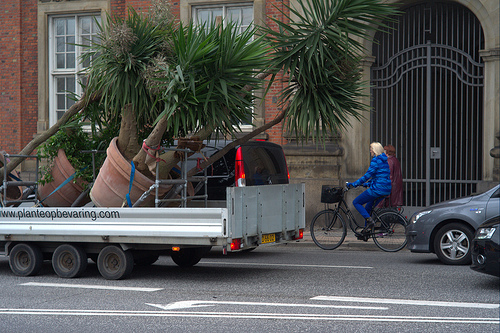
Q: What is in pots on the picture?
A: Palm trees.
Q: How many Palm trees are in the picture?
A: Six.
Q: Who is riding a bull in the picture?
A: No one.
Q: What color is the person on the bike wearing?
A: Blue.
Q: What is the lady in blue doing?
A: Riding a bike.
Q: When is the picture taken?
A: Daytime.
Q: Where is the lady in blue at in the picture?
A: In middle of picture.